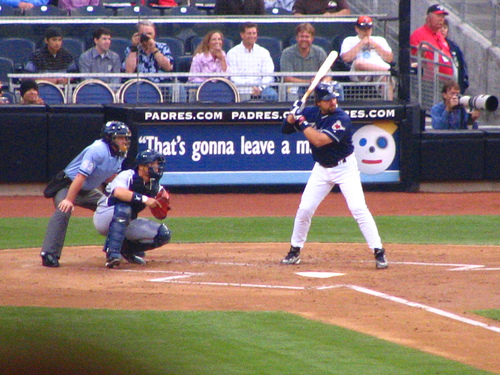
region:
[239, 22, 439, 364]
man playing baseball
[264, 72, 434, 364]
man wearing helmet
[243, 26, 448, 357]
a man wearing blue jersey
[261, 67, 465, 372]
man wearing baseball cliets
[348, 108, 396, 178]
jack in the box mascot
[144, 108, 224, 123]
ad for padres web site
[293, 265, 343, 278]
home plate on the baseball diamond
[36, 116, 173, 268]
catcher and umpire crouching and watching batter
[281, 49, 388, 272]
player up to bat wearing helmet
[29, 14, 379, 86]
fans with field side seats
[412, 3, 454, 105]
older man with padres hat on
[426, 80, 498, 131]
sports photographer with huge telephoto lens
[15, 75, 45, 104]
man with knit cap and beer watching the game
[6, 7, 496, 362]
A baseball game.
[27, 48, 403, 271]
Baseball players on the field.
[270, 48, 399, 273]
The batter is standing at the plate.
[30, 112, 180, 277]
The umpire stands behind the catcher.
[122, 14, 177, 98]
A man is taking photos.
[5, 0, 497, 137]
People in the stands.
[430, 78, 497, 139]
A man is using a large telephoto lens.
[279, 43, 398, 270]
The man is holding a baseball bat.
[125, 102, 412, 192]
An advertisement on the wall.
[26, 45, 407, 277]
The men are playing baseball on the field.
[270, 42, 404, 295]
Baseball batter standing at home plate with bat.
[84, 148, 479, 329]
Catcher squatting behind home plate.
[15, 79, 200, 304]
Referee standing behind catcher.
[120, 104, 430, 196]
Sign with a clown with black eye.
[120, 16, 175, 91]
Man wearing blue and white shirt taking pictures.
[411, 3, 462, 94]
Older man wearing red shirt and baseball cap.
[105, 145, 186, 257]
Catcher wearing mitt on right hand.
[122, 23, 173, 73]
A man taking a picture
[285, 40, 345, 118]
An upraised wooden baseball bat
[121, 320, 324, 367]
An area of green grass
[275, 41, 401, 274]
A baseball player is holding a bat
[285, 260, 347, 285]
Home plate is white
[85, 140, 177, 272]
A catcher is crouched down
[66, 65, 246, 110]
Three empty blue seats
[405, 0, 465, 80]
A man wearing a red shirt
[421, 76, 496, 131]
A man looking into a long lense camera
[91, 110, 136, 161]
Umpire wearing a face mask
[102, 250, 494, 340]
White lines on the dirt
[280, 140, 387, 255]
A pair of white pants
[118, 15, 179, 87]
A man is taking a picture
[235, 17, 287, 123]
A person sitting down.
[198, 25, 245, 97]
A person sitting down.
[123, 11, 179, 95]
A person sitting down.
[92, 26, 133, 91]
A person sitting down.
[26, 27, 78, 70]
A person sitting down.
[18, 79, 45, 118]
A person sitting down.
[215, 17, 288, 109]
A person sitting down.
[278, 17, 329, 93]
A person sitting down.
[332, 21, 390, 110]
A person sitting down.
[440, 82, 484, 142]
A person sitting down.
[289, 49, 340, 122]
The baseball player is holding a white bat.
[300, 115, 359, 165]
The baseball player is wearing a blue shirt.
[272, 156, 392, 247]
The baseball player is wearing white pants.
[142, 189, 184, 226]
The catcher is holding a glove in his hand.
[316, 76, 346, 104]
The baseball player is wearing a blue helmet.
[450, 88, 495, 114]
The man is holding a large lens camera.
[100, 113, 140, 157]
The umpire is wearing a helmet and a mask.